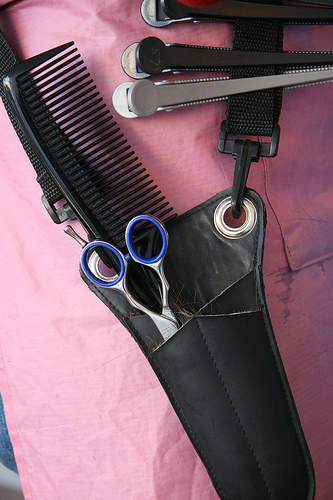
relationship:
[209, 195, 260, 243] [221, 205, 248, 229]
ring around hole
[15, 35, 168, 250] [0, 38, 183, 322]
tooth on comb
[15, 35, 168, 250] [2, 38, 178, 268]
tooth on comb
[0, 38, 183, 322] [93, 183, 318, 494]
comb in pouch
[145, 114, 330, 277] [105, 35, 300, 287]
apron under tools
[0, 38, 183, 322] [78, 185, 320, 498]
comb in case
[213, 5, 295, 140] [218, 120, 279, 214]
strap attached to clip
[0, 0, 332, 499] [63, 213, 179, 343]
apron with scissor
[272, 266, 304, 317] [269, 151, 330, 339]
stain on cloth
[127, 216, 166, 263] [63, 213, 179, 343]
ring around scissor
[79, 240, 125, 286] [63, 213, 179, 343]
ring around scissor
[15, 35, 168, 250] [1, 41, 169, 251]
tooth on comb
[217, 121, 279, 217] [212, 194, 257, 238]
plastic clip on ring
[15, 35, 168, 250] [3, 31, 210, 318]
tooth on comb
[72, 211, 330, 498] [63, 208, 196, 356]
pouch containing scissors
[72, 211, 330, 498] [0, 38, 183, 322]
pouch containing comb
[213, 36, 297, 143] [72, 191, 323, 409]
strap attached to pouch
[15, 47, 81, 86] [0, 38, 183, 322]
tooth on comb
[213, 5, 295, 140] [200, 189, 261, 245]
strap on hole